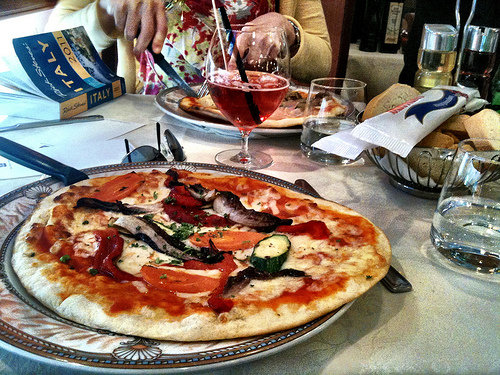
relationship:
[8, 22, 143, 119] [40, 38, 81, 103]
book about italy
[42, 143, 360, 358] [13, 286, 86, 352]
pizza on plate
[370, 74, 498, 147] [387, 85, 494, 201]
bread in basket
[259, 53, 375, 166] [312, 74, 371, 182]
glass of water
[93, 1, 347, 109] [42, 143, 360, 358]
woman eating pizza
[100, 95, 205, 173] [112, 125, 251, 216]
pair of sunglasses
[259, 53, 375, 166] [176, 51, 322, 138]
glass of juice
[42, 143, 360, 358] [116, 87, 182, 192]
pizza on tablecloth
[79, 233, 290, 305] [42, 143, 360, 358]
vegetable on pizza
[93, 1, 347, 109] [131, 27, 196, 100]
woman holding knife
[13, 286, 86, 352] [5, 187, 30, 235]
plate has designs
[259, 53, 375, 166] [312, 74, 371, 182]
glass with water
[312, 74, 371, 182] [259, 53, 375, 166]
water in glass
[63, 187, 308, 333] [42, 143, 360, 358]
cheese on pizza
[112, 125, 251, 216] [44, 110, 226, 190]
sunglasses on table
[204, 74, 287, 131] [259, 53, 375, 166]
juice in glass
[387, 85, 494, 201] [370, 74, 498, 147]
basket of bread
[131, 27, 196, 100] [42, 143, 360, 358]
knife under pizza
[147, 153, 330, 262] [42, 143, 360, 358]
tomatoes on pizza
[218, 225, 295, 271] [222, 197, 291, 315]
piece of squash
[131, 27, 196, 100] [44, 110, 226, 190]
knife on table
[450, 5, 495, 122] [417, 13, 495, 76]
vinegar in rack